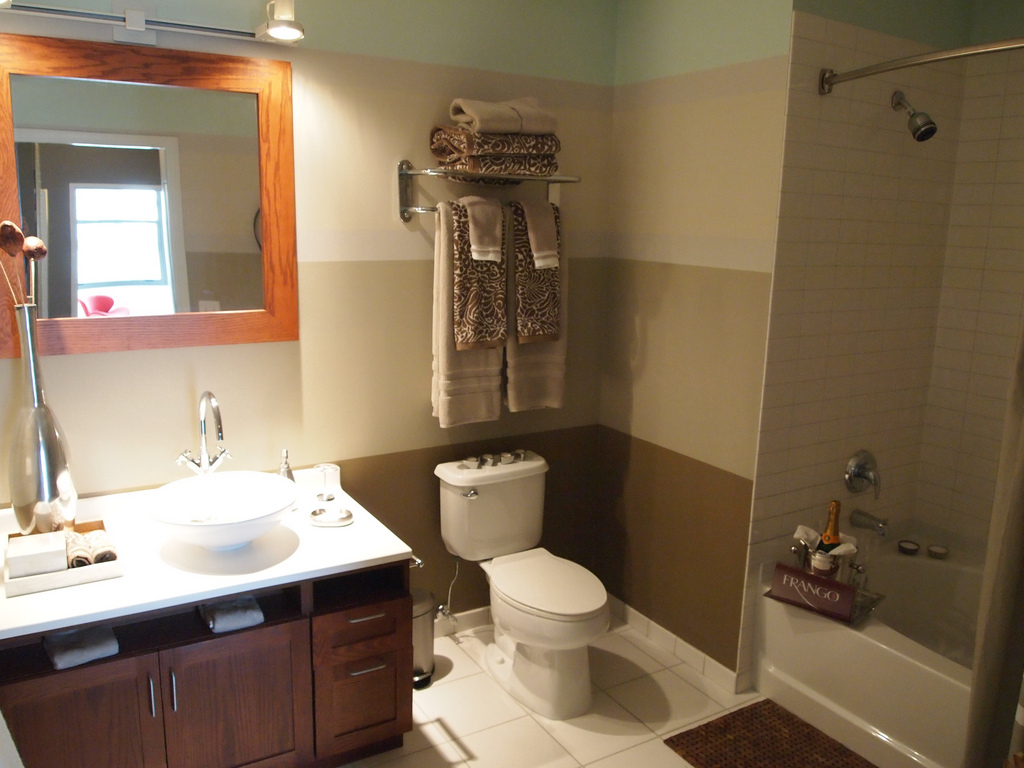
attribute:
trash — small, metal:
[411, 600, 435, 694]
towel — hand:
[43, 629, 123, 671]